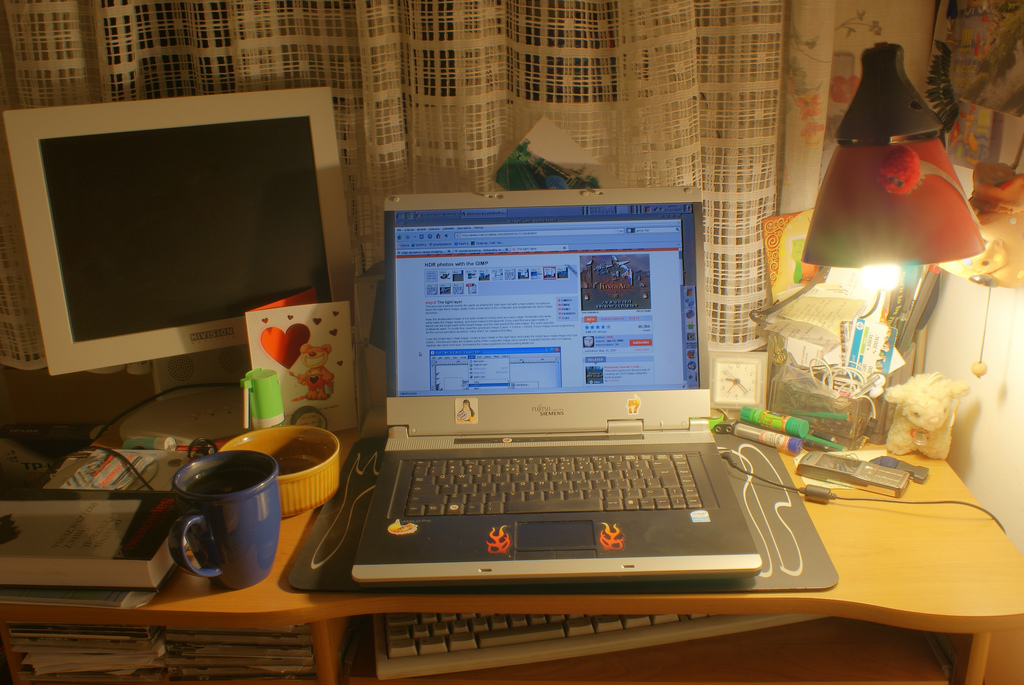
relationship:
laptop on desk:
[345, 184, 761, 592] [8, 361, 1021, 684]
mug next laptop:
[168, 447, 290, 585] [332, 156, 780, 600]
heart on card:
[256, 313, 315, 372] [240, 286, 378, 446]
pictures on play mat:
[717, 428, 817, 591] [282, 431, 834, 596]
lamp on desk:
[785, 32, 975, 285] [10, 399, 1022, 682]